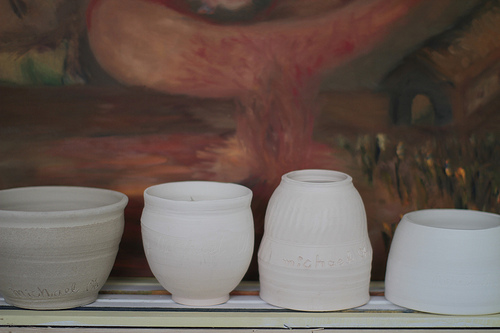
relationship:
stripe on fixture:
[1, 324, 499, 331] [0, 278, 497, 333]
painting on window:
[1, 6, 481, 177] [465, 63, 492, 118]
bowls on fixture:
[140, 179, 255, 306] [2, 277, 498, 327]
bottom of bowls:
[282, 161, 357, 193] [257, 168, 374, 311]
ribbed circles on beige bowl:
[0, 213, 127, 266] [0, 185, 129, 311]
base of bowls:
[256, 275, 374, 312] [257, 168, 374, 311]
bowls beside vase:
[141, 180, 255, 307] [256, 167, 374, 312]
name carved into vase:
[278, 245, 370, 269] [256, 167, 374, 312]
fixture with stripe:
[0, 278, 497, 333] [95, 286, 385, 298]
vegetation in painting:
[355, 125, 497, 219] [22, 4, 497, 225]